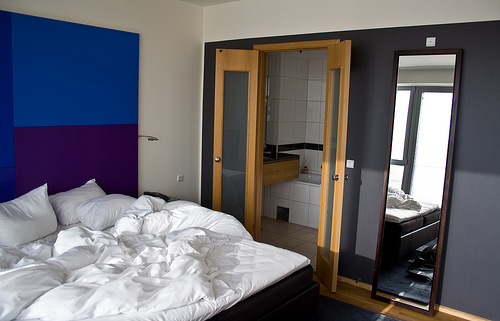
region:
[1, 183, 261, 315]
bed is not made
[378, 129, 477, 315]
mirror on the wall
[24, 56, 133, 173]
purple and blue on wall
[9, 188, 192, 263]
three pillows on bed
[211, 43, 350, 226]
brown doors to bathroom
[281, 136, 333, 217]
tub in the bathroom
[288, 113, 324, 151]
tile on bathroom wall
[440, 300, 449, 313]
wood work is brown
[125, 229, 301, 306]
the sheets are white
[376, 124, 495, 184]
reflection in the mirror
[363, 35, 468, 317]
A wall mirror with a reflection in it.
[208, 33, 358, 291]
Open wooden doors.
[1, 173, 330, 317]
An unmade bed with a fluffy comforter.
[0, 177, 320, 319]
A comfortable looking white comforter.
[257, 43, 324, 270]
The inside of a bathroom.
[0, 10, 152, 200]
A blue wall decoration behind a bed.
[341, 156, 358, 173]
A small object that looks like a light switch.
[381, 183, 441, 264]
A reflection of a bed in a mirror.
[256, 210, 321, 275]
A tan tile floor.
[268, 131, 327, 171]
A black line on the wall.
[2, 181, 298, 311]
the bed is messy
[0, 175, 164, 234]
3 pillows on the bed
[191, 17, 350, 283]
the doors are open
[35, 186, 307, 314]
the covers are white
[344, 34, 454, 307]
the mirror is tall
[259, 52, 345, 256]
the bathroom light is off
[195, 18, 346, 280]
the doors are tan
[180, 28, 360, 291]
the doors are made of wood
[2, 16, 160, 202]
the wall behind the bed is purple and blue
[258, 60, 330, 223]
the walls are made of tile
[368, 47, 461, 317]
a wall mirror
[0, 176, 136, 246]
three white pillows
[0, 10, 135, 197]
very tall headboard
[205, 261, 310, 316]
the bed's footboard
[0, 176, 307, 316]
white pillows and sheets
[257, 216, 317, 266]
floor of the bathroom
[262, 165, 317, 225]
part of the bathtub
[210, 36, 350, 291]
open doors and entrace to bathroom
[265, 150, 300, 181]
part of the bathroom counter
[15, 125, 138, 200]
purple square on the headboard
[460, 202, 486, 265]
gray paint on the wall.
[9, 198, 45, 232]
pillow on the bed.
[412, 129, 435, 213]
reflection in the mirror.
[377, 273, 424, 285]
mirror against the wall.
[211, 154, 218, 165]
handle on the door.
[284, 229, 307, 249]
tile on the floor.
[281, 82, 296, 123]
tile on the wall.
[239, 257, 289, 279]
sheets on the bed.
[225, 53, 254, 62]
door made of wood.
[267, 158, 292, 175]
sink in the bathroom.